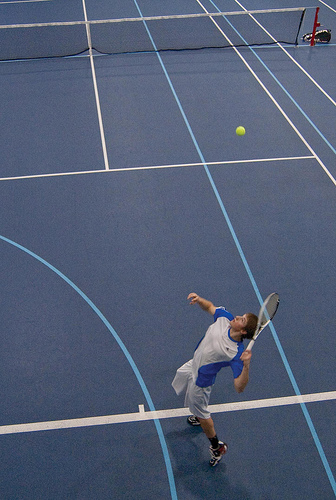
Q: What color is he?
A: White.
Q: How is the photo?
A: Clear.